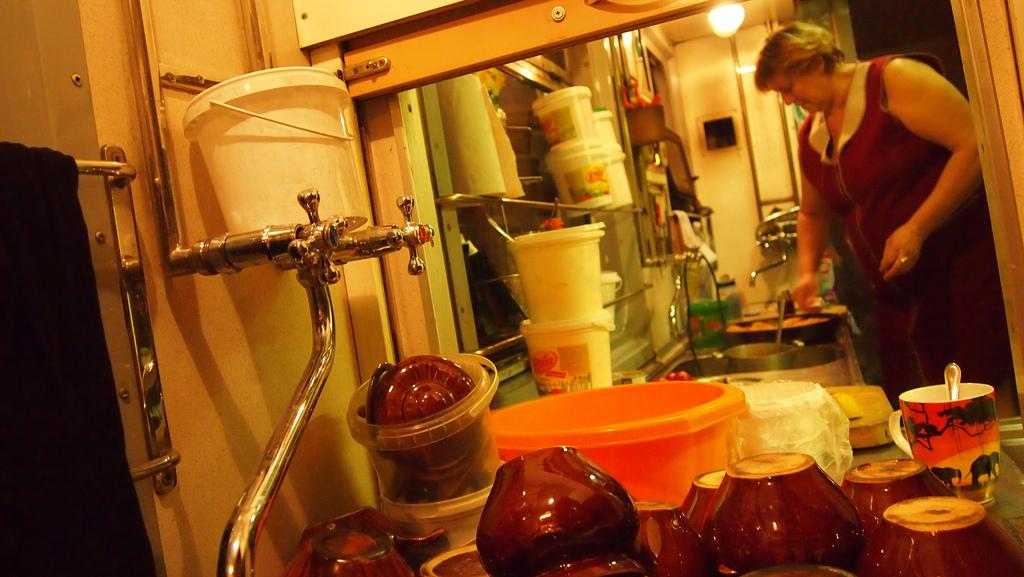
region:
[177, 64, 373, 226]
white bucket on the wall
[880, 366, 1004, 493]
mug on the table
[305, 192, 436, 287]
faucet knob on the pipe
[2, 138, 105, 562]
black towel hanging on the rack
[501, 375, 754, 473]
orange bowl on the table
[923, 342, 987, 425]
spoon in the mug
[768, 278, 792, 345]
utensil in the silver pot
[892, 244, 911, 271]
ring on the finger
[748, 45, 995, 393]
Woman is wearing red dress.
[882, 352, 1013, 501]
Spoon is inside the cup.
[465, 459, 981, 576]
Cup is brown color.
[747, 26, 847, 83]
Woman hair is brown color.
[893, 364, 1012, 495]
coffee mug on the counter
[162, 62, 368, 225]
white bucket next to the wall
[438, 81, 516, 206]
roll of paper towel on the shelf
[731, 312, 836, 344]
food in the frying pan on the counter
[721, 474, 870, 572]
object on the table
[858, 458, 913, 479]
object on the table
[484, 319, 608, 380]
object on the table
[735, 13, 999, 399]
this is a woman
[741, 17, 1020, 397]
woman wearing a dress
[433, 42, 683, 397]
a set of buckets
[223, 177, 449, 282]
a set of knobs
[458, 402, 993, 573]
a set of dishes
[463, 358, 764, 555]
a orange plastic bowl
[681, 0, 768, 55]
light on the ceiling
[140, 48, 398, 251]
a large white bucket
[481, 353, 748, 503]
a orange bowl on a table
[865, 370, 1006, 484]
coffee cup on the side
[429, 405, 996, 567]
a group of cups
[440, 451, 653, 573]
the cup is brown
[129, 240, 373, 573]
pipe on the side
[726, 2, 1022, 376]
a woman is standing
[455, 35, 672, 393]
a group of buckets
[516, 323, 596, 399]
label on the bucket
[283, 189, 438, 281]
two silver faucet handles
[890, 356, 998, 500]
utensil in coffee mug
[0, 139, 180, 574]
towel hanging from rack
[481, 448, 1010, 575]
ceramic bowls turned upside down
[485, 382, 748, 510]
side of orange bucket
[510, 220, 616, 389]
two stacked white buckets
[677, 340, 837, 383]
metal pan in sink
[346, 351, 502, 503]
ceramic bowl in plastic bucket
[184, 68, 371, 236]
white bucket with handle